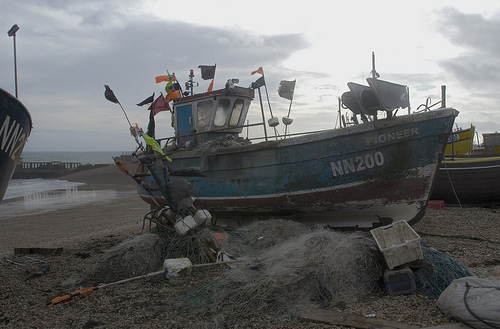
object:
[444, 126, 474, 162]
boat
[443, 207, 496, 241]
ground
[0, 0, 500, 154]
clouds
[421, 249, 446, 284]
netting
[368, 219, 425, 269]
bin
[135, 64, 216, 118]
flags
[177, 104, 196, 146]
door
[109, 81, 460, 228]
boat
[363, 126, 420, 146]
name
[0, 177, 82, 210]
water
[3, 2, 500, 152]
sky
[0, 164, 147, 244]
beach